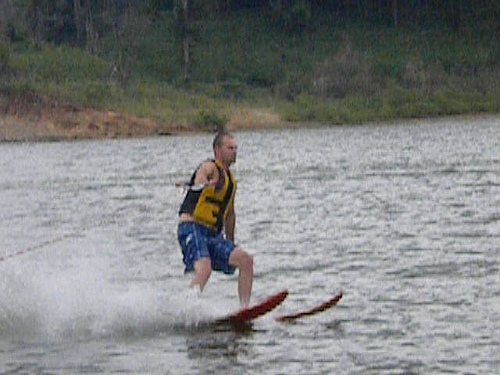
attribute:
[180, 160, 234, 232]
life vest — black, yellow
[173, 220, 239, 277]
shorts — blue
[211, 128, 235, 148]
hair — short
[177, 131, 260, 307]
man — dressed, water skiing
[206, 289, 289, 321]
skis — red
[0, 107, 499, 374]
water — light grey, splashing, foamy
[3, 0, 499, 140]
trees — green, on land